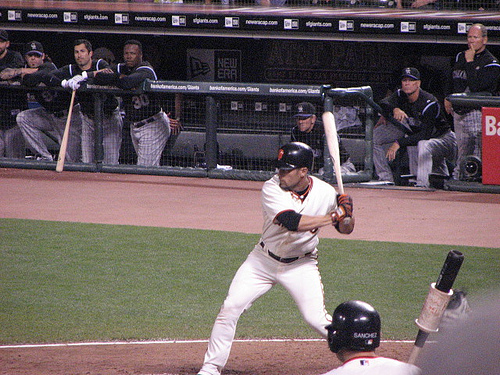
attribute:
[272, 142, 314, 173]
helmet —  black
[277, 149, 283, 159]
ornament —  red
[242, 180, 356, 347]
uniform — white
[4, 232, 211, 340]
grass — green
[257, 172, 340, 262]
jersey — white, orange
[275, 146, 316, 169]
helmet — black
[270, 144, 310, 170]
helmet — black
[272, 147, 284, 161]
logo — orange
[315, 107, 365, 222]
baseball bat — wooden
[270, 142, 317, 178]
helmet — black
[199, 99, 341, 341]
baseball player — batter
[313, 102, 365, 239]
bat — white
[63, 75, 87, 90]
hands — gloved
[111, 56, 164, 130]
jersey — black and white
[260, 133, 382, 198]
helmet — black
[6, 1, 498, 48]
dugout roof — pictured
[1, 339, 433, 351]
line — white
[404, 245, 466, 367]
bat —  black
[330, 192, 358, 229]
gloves — orange and black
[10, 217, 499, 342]
grass — green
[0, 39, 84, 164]
team member — opposing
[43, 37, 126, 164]
team member — opposing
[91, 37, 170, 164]
team member — opposing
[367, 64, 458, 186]
team member — opposing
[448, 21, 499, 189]
team member — opposing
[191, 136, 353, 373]
batter — swing-ready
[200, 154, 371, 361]
man — baseball player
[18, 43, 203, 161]
team — opposing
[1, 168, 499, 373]
dirt — brown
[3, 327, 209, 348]
line — white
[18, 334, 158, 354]
line — white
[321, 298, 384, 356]
helmet —  black